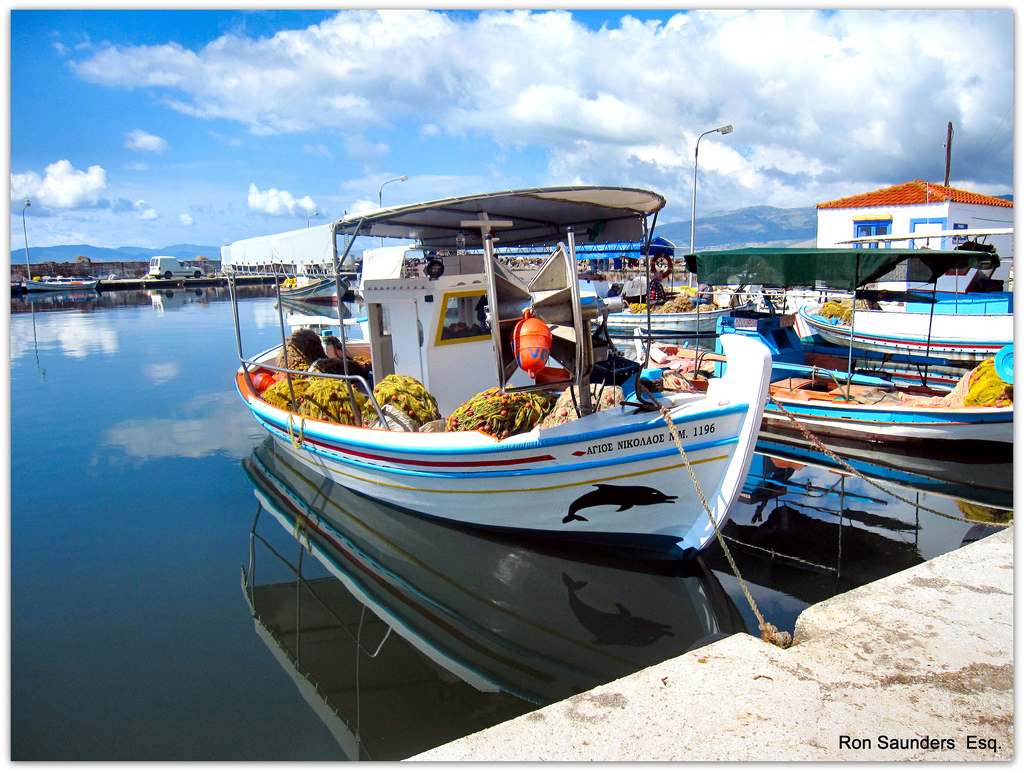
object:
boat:
[219, 186, 769, 550]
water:
[0, 304, 1011, 755]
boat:
[764, 346, 1013, 461]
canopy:
[219, 186, 670, 278]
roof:
[813, 180, 1015, 211]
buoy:
[514, 318, 550, 379]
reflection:
[243, 434, 750, 760]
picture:
[562, 483, 679, 522]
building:
[818, 180, 1015, 249]